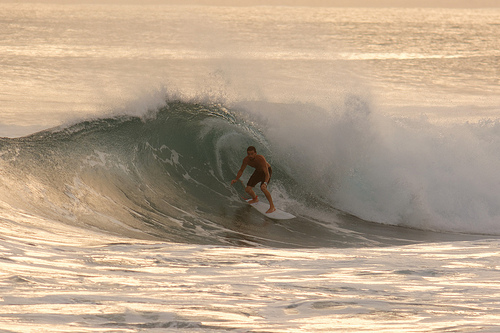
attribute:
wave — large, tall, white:
[15, 104, 495, 246]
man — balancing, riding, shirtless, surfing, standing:
[229, 143, 283, 211]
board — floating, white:
[242, 194, 299, 226]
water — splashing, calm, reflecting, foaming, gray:
[3, 2, 498, 327]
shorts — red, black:
[242, 168, 275, 191]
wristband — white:
[259, 180, 268, 185]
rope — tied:
[252, 187, 265, 203]